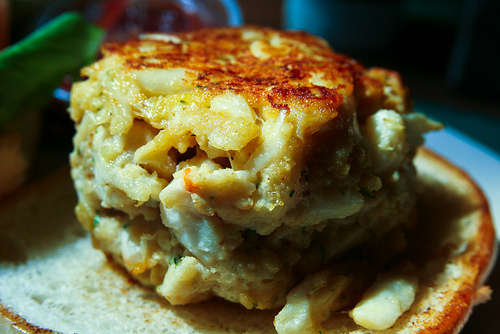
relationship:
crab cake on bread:
[64, 21, 446, 333] [0, 144, 495, 333]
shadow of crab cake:
[168, 176, 472, 333] [64, 21, 446, 333]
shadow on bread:
[168, 176, 472, 333] [0, 144, 495, 333]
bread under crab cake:
[0, 144, 495, 333] [64, 21, 446, 333]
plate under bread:
[2, 109, 499, 332] [0, 144, 495, 333]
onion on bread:
[348, 257, 420, 329] [0, 144, 495, 333]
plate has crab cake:
[2, 109, 499, 332] [64, 21, 446, 333]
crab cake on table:
[64, 21, 446, 333] [405, 98, 499, 334]